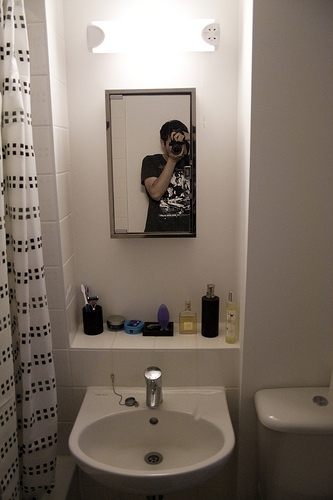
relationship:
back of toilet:
[258, 387, 328, 485] [246, 377, 331, 498]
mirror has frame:
[112, 94, 192, 231] [103, 87, 201, 244]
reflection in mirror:
[134, 110, 188, 230] [112, 94, 192, 231]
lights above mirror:
[83, 14, 232, 62] [112, 94, 192, 231]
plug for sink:
[106, 369, 140, 410] [66, 364, 242, 492]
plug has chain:
[106, 369, 140, 410] [109, 366, 125, 407]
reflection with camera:
[134, 110, 188, 230] [166, 133, 190, 158]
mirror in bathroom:
[112, 94, 192, 231] [1, 3, 331, 500]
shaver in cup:
[85, 296, 101, 310] [83, 304, 106, 338]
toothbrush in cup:
[77, 283, 89, 306] [83, 304, 106, 338]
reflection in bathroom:
[134, 110, 188, 230] [1, 3, 331, 500]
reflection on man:
[134, 110, 188, 230] [133, 112, 191, 226]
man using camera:
[133, 112, 191, 226] [166, 133, 190, 158]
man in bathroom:
[133, 112, 191, 226] [1, 3, 331, 500]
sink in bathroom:
[66, 364, 242, 492] [1, 3, 331, 500]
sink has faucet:
[66, 364, 242, 492] [136, 359, 169, 410]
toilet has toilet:
[246, 377, 331, 498] [251, 384, 333, 499]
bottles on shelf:
[176, 285, 240, 351] [73, 311, 248, 360]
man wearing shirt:
[133, 112, 191, 226] [139, 154, 192, 231]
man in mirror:
[133, 112, 191, 226] [112, 94, 192, 231]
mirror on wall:
[112, 94, 192, 231] [27, 7, 325, 391]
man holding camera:
[133, 112, 191, 226] [166, 133, 190, 158]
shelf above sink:
[73, 311, 248, 360] [66, 364, 242, 492]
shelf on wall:
[73, 311, 248, 360] [27, 7, 325, 391]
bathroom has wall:
[1, 3, 331, 500] [27, 7, 325, 391]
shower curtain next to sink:
[1, 0, 65, 498] [66, 364, 242, 492]